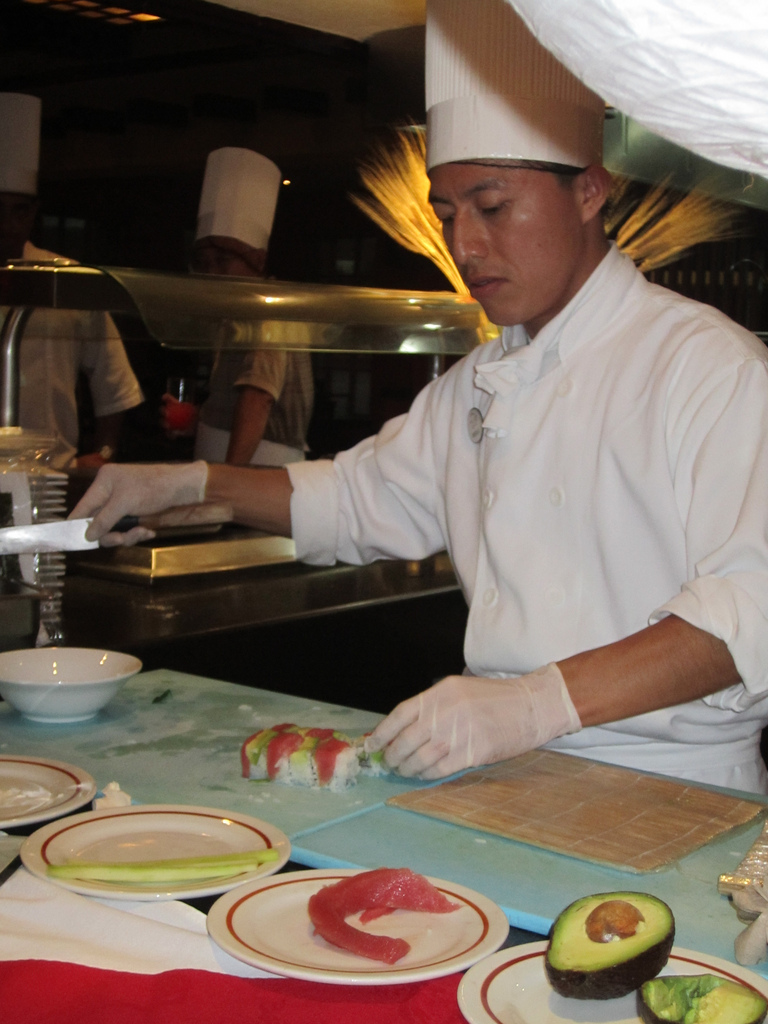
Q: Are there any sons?
A: No, there are no sons.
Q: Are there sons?
A: No, there are no sons.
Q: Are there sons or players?
A: No, there are no sons or players.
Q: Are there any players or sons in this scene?
A: No, there are no sons or players.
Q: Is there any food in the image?
A: Yes, there is food.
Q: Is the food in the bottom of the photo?
A: Yes, the food is in the bottom of the image.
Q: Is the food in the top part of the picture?
A: No, the food is in the bottom of the image.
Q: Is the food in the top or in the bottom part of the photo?
A: The food is in the bottom of the image.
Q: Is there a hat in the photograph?
A: Yes, there is a hat.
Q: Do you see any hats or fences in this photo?
A: Yes, there is a hat.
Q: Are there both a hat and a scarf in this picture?
A: No, there is a hat but no scarves.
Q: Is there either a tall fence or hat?
A: Yes, there is a tall hat.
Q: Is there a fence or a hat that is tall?
A: Yes, the hat is tall.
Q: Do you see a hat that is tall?
A: Yes, there is a tall hat.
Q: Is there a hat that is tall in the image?
A: Yes, there is a tall hat.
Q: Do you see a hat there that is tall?
A: Yes, there is a hat that is tall.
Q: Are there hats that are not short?
A: Yes, there is a tall hat.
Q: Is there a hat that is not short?
A: Yes, there is a tall hat.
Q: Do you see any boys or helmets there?
A: No, there are no helmets or boys.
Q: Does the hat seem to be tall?
A: Yes, the hat is tall.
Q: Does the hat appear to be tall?
A: Yes, the hat is tall.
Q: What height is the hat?
A: The hat is tall.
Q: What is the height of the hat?
A: The hat is tall.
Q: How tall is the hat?
A: The hat is tall.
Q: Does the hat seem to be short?
A: No, the hat is tall.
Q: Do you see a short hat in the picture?
A: No, there is a hat but it is tall.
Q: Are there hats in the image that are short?
A: No, there is a hat but it is tall.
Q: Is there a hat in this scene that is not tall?
A: No, there is a hat but it is tall.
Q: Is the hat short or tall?
A: The hat is tall.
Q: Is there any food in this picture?
A: Yes, there is food.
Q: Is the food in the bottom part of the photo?
A: Yes, the food is in the bottom of the image.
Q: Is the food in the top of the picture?
A: No, the food is in the bottom of the image.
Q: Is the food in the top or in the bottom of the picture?
A: The food is in the bottom of the image.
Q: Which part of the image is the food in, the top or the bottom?
A: The food is in the bottom of the image.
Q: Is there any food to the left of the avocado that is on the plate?
A: Yes, there is food to the left of the avocado.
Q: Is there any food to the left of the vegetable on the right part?
A: Yes, there is food to the left of the avocado.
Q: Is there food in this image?
A: Yes, there is food.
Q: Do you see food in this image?
A: Yes, there is food.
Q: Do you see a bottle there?
A: No, there are no bottles.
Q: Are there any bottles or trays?
A: No, there are no bottles or trays.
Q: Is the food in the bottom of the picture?
A: Yes, the food is in the bottom of the image.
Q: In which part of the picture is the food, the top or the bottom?
A: The food is in the bottom of the image.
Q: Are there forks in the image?
A: No, there are no forks.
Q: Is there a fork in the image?
A: No, there are no forks.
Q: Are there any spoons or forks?
A: No, there are no forks or spoons.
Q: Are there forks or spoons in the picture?
A: No, there are no forks or spoons.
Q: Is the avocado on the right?
A: Yes, the avocado is on the right of the image.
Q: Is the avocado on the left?
A: No, the avocado is on the right of the image.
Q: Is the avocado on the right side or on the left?
A: The avocado is on the right of the image.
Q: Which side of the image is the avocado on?
A: The avocado is on the right of the image.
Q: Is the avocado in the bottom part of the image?
A: Yes, the avocado is in the bottom of the image.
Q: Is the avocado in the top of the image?
A: No, the avocado is in the bottom of the image.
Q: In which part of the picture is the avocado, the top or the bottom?
A: The avocado is in the bottom of the image.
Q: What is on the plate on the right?
A: The avocado is on the plate.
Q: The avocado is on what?
A: The avocado is on the plate.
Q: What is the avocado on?
A: The avocado is on the plate.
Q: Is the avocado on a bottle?
A: No, the avocado is on the plate.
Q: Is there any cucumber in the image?
A: Yes, there is a cucumber.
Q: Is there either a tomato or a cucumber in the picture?
A: Yes, there is a cucumber.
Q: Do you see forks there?
A: No, there are no forks.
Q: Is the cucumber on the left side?
A: Yes, the cucumber is on the left of the image.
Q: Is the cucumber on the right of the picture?
A: No, the cucumber is on the left of the image.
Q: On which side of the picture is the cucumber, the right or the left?
A: The cucumber is on the left of the image.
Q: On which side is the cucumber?
A: The cucumber is on the left of the image.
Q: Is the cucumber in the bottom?
A: Yes, the cucumber is in the bottom of the image.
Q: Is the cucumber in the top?
A: No, the cucumber is in the bottom of the image.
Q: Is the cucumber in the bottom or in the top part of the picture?
A: The cucumber is in the bottom of the image.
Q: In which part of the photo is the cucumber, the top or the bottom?
A: The cucumber is in the bottom of the image.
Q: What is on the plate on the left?
A: The cucumber is on the plate.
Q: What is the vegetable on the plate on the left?
A: The vegetable is a cucumber.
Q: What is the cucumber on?
A: The cucumber is on the plate.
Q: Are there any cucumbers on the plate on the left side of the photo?
A: Yes, there is a cucumber on the plate.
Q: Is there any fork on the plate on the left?
A: No, there is a cucumber on the plate.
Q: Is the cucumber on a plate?
A: Yes, the cucumber is on a plate.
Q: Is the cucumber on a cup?
A: No, the cucumber is on a plate.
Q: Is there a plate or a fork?
A: Yes, there is a plate.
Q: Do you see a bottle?
A: No, there are no bottles.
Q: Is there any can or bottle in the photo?
A: No, there are no bottles or cans.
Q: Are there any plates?
A: Yes, there is a plate.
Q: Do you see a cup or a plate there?
A: Yes, there is a plate.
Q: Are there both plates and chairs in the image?
A: No, there is a plate but no chairs.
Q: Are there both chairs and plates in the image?
A: No, there is a plate but no chairs.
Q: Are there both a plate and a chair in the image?
A: No, there is a plate but no chairs.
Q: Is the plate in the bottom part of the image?
A: Yes, the plate is in the bottom of the image.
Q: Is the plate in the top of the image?
A: No, the plate is in the bottom of the image.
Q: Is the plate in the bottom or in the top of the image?
A: The plate is in the bottom of the image.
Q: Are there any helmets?
A: No, there are no helmets.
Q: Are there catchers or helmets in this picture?
A: No, there are no helmets or catchers.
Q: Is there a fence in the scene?
A: No, there are no fences.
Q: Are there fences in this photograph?
A: No, there are no fences.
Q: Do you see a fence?
A: No, there are no fences.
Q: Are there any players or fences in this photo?
A: No, there are no fences or players.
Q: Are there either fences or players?
A: No, there are no fences or players.